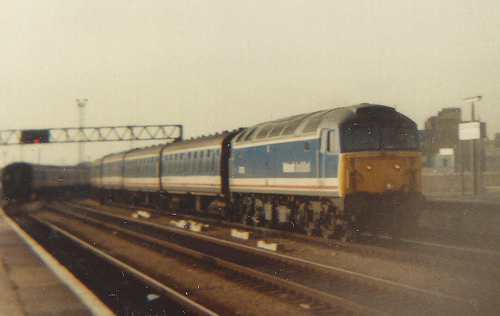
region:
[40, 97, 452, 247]
This is a train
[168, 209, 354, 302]
The tracks are made of steel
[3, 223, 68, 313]
Platform for passengers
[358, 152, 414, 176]
Two headlights on the front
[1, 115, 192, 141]
Metal object over the train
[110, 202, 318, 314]
Rocks surrounding the train tracks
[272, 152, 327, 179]
White text on the train's side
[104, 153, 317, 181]
Windows along the side of the train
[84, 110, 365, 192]
This is a passenger train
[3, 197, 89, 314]
White line along the edge of the platform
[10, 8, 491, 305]
Picture taken many decades ago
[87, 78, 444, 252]
The train is on train tracks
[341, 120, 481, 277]
Dirt blown into the air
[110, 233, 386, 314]
Train tracks made of steel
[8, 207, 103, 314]
White line at the edge of the platform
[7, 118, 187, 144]
Metal object above train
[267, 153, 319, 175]
Words on the side of the train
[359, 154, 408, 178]
Two headlights on the front of the train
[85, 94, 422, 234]
blue and yellow train on the tracks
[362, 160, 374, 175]
head light on the front of the train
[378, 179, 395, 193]
head light on the front of the train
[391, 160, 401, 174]
head light on the front of the train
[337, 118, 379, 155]
window on the train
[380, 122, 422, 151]
window on the train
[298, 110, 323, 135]
window on the train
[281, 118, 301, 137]
window on the train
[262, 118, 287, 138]
window on the train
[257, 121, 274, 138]
window on the train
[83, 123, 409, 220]
train pulling into the station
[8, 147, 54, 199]
train pulling into the station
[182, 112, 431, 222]
train pulling into the station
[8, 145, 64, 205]
train pulling into the station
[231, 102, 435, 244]
train pulling into the station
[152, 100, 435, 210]
train pulling into the station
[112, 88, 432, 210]
train pulling into the station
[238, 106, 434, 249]
train pulling into the station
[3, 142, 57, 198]
train pulling into the station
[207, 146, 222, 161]
Small window on a train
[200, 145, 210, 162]
Small window on a train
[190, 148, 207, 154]
Small window on a train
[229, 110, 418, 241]
Blue and white train engine on tracks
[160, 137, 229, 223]
Blue and white train catts on a track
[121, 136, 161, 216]
Blue and white train catts on a track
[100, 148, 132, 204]
Blue and white train catts on a track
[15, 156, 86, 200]
Blue and white train catts on a track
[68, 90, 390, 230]
Large blue and white trains on tracks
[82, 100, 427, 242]
a long train on a track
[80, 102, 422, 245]
a train on the rails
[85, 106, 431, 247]
a train travelling on a track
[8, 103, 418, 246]
two trains on a track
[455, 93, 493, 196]
a pole with a sign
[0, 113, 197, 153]
a metal post over the tracks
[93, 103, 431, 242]
a big train on the tracks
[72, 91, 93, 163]
a tall radio tower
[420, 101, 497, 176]
buildings in the horizon